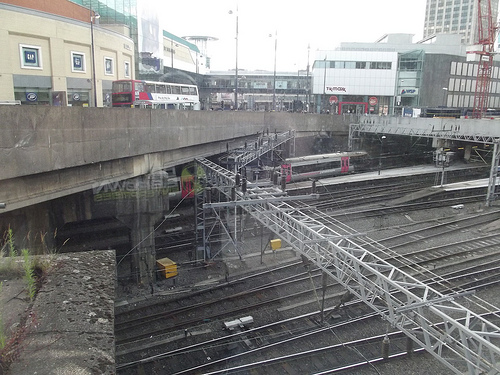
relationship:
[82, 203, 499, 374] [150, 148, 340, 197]
tracks are for train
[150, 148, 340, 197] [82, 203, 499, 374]
train on tracks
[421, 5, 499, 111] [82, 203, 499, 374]
building are above tracks